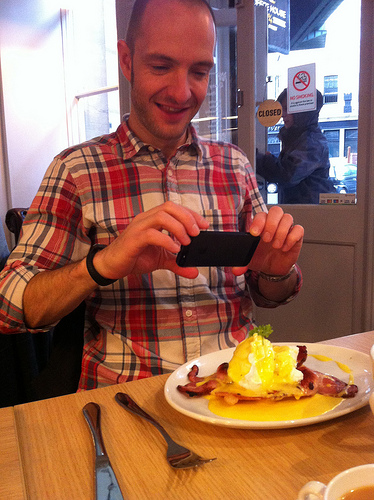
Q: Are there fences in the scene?
A: No, there are no fences.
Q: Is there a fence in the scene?
A: No, there are no fences.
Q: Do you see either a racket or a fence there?
A: No, there are no fences or rackets.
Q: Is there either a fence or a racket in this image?
A: No, there are no fences or rackets.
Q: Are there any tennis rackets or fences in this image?
A: No, there are no fences or tennis rackets.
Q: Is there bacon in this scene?
A: Yes, there is bacon.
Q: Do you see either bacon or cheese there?
A: Yes, there is bacon.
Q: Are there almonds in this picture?
A: No, there are no almonds.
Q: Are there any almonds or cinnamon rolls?
A: No, there are no almonds or cinnamon rolls.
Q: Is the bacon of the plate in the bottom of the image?
A: Yes, the bacon is in the bottom of the image.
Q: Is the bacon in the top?
A: No, the bacon is in the bottom of the image.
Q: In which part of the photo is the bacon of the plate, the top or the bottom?
A: The bacon is in the bottom of the image.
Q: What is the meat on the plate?
A: The meat is bacon.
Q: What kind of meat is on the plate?
A: The meat is bacon.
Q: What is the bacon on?
A: The bacon is on the plate.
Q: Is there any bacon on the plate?
A: Yes, there is bacon on the plate.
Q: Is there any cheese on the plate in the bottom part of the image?
A: No, there is bacon on the plate.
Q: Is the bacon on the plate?
A: Yes, the bacon is on the plate.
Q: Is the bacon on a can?
A: No, the bacon is on the plate.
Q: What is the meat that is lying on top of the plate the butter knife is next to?
A: The meat is bacon.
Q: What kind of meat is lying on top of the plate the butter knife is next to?
A: The meat is bacon.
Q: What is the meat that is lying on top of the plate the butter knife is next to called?
A: The meat is bacon.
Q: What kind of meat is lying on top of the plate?
A: The meat is bacon.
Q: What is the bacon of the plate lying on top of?
A: The bacon is lying on top of the plate.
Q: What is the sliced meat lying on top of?
A: The bacon is lying on top of the plate.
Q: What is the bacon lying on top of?
A: The bacon is lying on top of the plate.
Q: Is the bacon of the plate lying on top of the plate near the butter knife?
A: Yes, the bacon is lying on top of the plate.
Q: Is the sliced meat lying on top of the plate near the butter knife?
A: Yes, the bacon is lying on top of the plate.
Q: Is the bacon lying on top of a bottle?
A: No, the bacon is lying on top of the plate.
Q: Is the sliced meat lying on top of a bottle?
A: No, the bacon is lying on top of the plate.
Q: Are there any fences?
A: No, there are no fences.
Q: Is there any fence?
A: No, there are no fences.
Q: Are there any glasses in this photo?
A: No, there are no glasses.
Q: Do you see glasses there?
A: No, there are no glasses.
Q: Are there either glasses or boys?
A: No, there are no glasses or boys.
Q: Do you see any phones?
A: Yes, there is a phone.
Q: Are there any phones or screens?
A: Yes, there is a phone.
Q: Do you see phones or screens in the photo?
A: Yes, there is a phone.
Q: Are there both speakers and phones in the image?
A: No, there is a phone but no speakers.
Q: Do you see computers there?
A: No, there are no computers.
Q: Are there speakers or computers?
A: No, there are no computers or speakers.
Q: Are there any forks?
A: Yes, there is a fork.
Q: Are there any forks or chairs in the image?
A: Yes, there is a fork.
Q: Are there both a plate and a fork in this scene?
A: Yes, there are both a fork and a plate.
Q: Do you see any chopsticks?
A: No, there are no chopsticks.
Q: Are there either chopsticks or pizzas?
A: No, there are no chopsticks or pizzas.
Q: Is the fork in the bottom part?
A: Yes, the fork is in the bottom of the image.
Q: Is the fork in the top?
A: No, the fork is in the bottom of the image.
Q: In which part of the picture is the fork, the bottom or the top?
A: The fork is in the bottom of the image.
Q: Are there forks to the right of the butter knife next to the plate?
A: Yes, there is a fork to the right of the butter knife.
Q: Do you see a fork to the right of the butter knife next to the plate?
A: Yes, there is a fork to the right of the butter knife.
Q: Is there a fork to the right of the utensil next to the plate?
A: Yes, there is a fork to the right of the butter knife.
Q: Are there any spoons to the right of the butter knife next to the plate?
A: No, there is a fork to the right of the butter knife.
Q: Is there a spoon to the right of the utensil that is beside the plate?
A: No, there is a fork to the right of the butter knife.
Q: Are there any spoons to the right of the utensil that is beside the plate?
A: No, there is a fork to the right of the butter knife.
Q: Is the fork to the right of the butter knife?
A: Yes, the fork is to the right of the butter knife.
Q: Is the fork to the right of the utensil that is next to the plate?
A: Yes, the fork is to the right of the butter knife.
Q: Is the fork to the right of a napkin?
A: No, the fork is to the right of the butter knife.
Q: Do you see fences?
A: No, there are no fences.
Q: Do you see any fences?
A: No, there are no fences.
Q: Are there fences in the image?
A: No, there are no fences.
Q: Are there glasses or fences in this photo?
A: No, there are no fences or glasses.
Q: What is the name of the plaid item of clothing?
A: The clothing item is a shirt.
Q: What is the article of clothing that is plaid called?
A: The clothing item is a shirt.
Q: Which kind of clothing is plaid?
A: The clothing is a shirt.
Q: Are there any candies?
A: No, there are no candies.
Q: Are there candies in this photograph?
A: No, there are no candies.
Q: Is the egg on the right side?
A: Yes, the egg is on the right of the image.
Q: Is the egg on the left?
A: No, the egg is on the right of the image.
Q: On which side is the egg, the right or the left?
A: The egg is on the right of the image.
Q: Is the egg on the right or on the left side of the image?
A: The egg is on the right of the image.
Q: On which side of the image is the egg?
A: The egg is on the right of the image.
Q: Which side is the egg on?
A: The egg is on the right of the image.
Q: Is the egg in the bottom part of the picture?
A: Yes, the egg is in the bottom of the image.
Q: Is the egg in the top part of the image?
A: No, the egg is in the bottom of the image.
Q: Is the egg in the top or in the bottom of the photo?
A: The egg is in the bottom of the image.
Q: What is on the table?
A: The egg is on the table.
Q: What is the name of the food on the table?
A: The food is an egg.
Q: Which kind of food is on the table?
A: The food is an egg.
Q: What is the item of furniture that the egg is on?
A: The piece of furniture is a table.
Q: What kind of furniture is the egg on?
A: The egg is on the table.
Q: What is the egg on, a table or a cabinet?
A: The egg is on a table.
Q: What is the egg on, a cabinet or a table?
A: The egg is on a table.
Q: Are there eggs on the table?
A: Yes, there is an egg on the table.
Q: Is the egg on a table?
A: Yes, the egg is on a table.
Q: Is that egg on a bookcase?
A: No, the egg is on a table.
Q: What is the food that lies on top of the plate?
A: The food is an egg.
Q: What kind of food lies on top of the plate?
A: The food is an egg.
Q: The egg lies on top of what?
A: The egg lies on top of the plate.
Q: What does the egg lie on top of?
A: The egg lies on top of the plate.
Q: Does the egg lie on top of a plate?
A: Yes, the egg lies on top of a plate.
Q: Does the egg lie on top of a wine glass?
A: No, the egg lies on top of a plate.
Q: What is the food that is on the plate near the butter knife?
A: The food is an egg.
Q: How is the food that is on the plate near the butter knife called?
A: The food is an egg.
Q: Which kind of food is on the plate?
A: The food is an egg.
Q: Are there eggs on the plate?
A: Yes, there is an egg on the plate.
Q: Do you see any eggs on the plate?
A: Yes, there is an egg on the plate.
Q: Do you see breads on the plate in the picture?
A: No, there is an egg on the plate.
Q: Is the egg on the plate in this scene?
A: Yes, the egg is on the plate.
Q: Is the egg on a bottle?
A: No, the egg is on the plate.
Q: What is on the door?
A: The sign is on the door.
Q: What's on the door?
A: The sign is on the door.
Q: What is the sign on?
A: The sign is on the door.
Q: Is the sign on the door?
A: Yes, the sign is on the door.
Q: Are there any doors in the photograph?
A: Yes, there is a door.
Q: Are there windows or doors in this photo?
A: Yes, there is a door.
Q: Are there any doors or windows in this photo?
A: Yes, there is a door.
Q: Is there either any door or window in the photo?
A: Yes, there is a door.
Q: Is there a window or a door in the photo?
A: Yes, there is a door.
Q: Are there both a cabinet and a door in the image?
A: No, there is a door but no cabinets.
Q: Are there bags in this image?
A: No, there are no bags.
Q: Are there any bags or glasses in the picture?
A: No, there are no bags or glasses.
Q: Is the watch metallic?
A: Yes, the watch is metallic.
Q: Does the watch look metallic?
A: Yes, the watch is metallic.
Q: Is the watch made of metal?
A: Yes, the watch is made of metal.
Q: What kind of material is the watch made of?
A: The watch is made of metal.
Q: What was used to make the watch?
A: The watch is made of metal.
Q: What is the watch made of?
A: The watch is made of metal.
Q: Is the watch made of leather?
A: No, the watch is made of metal.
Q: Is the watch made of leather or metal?
A: The watch is made of metal.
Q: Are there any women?
A: Yes, there is a woman.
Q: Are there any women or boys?
A: Yes, there is a woman.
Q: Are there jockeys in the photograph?
A: No, there are no jockeys.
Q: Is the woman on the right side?
A: Yes, the woman is on the right of the image.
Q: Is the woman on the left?
A: No, the woman is on the right of the image.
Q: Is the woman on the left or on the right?
A: The woman is on the right of the image.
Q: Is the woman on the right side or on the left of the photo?
A: The woman is on the right of the image.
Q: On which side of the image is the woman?
A: The woman is on the right of the image.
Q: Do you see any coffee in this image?
A: Yes, there is coffee.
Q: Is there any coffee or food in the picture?
A: Yes, there is coffee.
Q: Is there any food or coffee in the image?
A: Yes, there is coffee.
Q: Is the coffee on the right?
A: Yes, the coffee is on the right of the image.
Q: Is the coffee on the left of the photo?
A: No, the coffee is on the right of the image.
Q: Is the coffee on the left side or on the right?
A: The coffee is on the right of the image.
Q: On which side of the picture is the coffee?
A: The coffee is on the right of the image.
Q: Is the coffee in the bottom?
A: Yes, the coffee is in the bottom of the image.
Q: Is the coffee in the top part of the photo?
A: No, the coffee is in the bottom of the image.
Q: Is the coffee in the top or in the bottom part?
A: The coffee is in the bottom of the image.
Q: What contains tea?
A: The coffee contains tea.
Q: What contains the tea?
A: The coffee contains tea.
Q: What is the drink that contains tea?
A: The drink is coffee.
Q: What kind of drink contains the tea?
A: The drink is coffee.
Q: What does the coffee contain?
A: The coffee contains tea.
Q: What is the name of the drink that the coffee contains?
A: The drink is tea.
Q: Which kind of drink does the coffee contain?
A: The coffee contains tea.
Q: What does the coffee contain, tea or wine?
A: The coffee contains tea.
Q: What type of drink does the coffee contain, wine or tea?
A: The coffee contains tea.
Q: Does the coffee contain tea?
A: Yes, the coffee contains tea.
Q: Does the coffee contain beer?
A: No, the coffee contains tea.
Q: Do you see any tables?
A: Yes, there is a table.